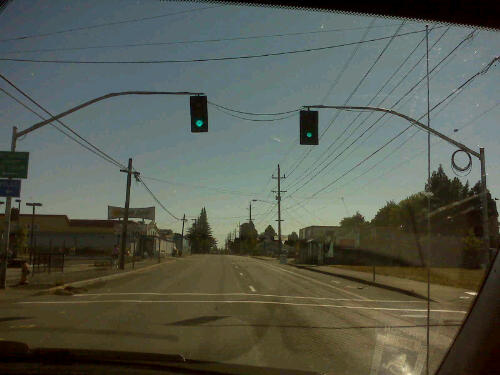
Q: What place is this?
A: It is a road.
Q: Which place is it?
A: It is a road.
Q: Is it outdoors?
A: Yes, it is outdoors.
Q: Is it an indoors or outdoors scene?
A: It is outdoors.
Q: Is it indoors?
A: No, it is outdoors.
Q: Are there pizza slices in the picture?
A: No, there are no pizza slices.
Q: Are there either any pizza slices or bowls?
A: No, there are no pizza slices or bowls.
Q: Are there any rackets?
A: No, there are no rackets.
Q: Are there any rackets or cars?
A: No, there are no rackets or cars.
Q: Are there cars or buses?
A: No, there are no cars or buses.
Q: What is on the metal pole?
A: The sign is on the pole.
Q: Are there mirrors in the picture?
A: No, there are no mirrors.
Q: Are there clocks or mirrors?
A: No, there are no mirrors or clocks.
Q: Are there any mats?
A: No, there are no mats.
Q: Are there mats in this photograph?
A: No, there are no mats.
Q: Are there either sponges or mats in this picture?
A: No, there are no mats or sponges.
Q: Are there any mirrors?
A: No, there are no mirrors.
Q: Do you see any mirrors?
A: No, there are no mirrors.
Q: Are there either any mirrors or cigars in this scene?
A: No, there are no mirrors or cigars.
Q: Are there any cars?
A: No, there are no cars.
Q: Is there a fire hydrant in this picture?
A: Yes, there is a fire hydrant.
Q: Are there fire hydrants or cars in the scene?
A: Yes, there is a fire hydrant.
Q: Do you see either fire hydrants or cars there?
A: Yes, there is a fire hydrant.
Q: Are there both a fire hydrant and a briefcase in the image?
A: No, there is a fire hydrant but no briefcases.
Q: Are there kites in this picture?
A: No, there are no kites.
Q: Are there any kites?
A: No, there are no kites.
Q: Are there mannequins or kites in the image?
A: No, there are no kites or mannequins.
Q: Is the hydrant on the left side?
A: Yes, the hydrant is on the left of the image.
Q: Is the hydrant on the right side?
A: No, the hydrant is on the left of the image.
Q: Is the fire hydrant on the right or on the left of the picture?
A: The fire hydrant is on the left of the image.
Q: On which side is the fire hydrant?
A: The fire hydrant is on the left of the image.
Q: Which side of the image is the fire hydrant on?
A: The fire hydrant is on the left of the image.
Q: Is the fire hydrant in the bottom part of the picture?
A: Yes, the fire hydrant is in the bottom of the image.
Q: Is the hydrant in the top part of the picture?
A: No, the hydrant is in the bottom of the image.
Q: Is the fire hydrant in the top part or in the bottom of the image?
A: The fire hydrant is in the bottom of the image.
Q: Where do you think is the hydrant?
A: The hydrant is on the side walk.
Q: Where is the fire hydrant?
A: The hydrant is on the side walk.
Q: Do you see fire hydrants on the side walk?
A: Yes, there is a fire hydrant on the side walk.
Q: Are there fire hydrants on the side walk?
A: Yes, there is a fire hydrant on the side walk.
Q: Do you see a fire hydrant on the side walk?
A: Yes, there is a fire hydrant on the side walk.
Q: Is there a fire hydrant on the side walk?
A: Yes, there is a fire hydrant on the side walk.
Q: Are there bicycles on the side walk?
A: No, there is a fire hydrant on the side walk.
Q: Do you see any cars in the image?
A: No, there are no cars.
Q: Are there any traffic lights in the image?
A: Yes, there is a traffic light.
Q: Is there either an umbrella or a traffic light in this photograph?
A: Yes, there is a traffic light.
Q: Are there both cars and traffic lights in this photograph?
A: No, there is a traffic light but no cars.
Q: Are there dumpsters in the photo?
A: No, there are no dumpsters.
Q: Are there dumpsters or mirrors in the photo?
A: No, there are no dumpsters or mirrors.